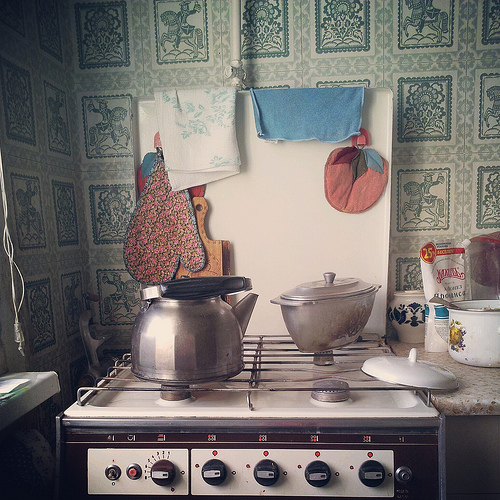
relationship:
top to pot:
[360, 338, 464, 391] [430, 273, 480, 347]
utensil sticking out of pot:
[429, 284, 460, 316] [437, 313, 498, 344]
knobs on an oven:
[204, 452, 386, 492] [55, 322, 443, 494]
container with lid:
[270, 272, 385, 352] [272, 265, 374, 295]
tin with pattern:
[385, 285, 427, 345] [388, 298, 421, 328]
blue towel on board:
[248, 86, 367, 141] [138, 91, 388, 328]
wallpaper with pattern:
[386, 25, 476, 156] [220, 0, 378, 68]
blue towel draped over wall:
[248, 86, 367, 141] [133, 80, 393, 347]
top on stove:
[360, 346, 459, 391] [61, 331, 451, 498]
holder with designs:
[324, 126, 391, 216] [344, 135, 401, 201]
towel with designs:
[125, 57, 242, 214] [341, 133, 389, 184]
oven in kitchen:
[65, 362, 440, 499] [8, 35, 495, 492]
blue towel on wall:
[248, 86, 367, 141] [66, 73, 466, 331]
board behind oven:
[146, 105, 403, 341] [102, 282, 442, 453]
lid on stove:
[77, 251, 241, 375] [97, 333, 419, 459]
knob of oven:
[201, 460, 228, 486] [67, 290, 446, 495]